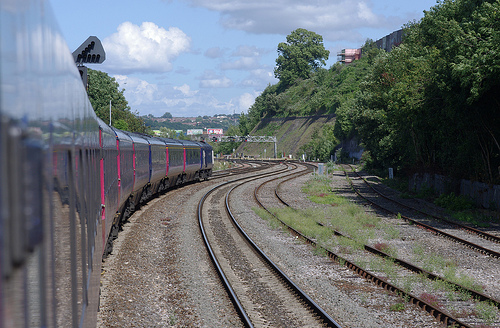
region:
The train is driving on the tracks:
[36, 63, 303, 289]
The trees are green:
[323, 54, 494, 201]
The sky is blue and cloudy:
[86, 17, 297, 139]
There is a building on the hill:
[314, 29, 436, 84]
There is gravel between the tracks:
[206, 196, 412, 306]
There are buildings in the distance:
[158, 118, 243, 146]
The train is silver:
[149, 135, 249, 198]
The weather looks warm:
[66, 17, 427, 282]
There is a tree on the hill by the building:
[265, 26, 367, 111]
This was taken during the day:
[66, 21, 313, 193]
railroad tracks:
[80, 212, 267, 322]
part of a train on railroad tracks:
[0, 3, 214, 326]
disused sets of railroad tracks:
[260, 175, 455, 273]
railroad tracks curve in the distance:
[215, 155, 310, 195]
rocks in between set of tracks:
[215, 220, 245, 275]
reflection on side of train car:
[5, 96, 110, 291]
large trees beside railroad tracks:
[356, 5, 493, 241]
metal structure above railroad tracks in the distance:
[183, 128, 294, 168]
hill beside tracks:
[255, 22, 492, 190]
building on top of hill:
[327, 38, 397, 88]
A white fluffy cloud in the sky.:
[103, 17, 192, 78]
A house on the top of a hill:
[336, 40, 368, 66]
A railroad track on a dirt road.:
[195, 202, 311, 326]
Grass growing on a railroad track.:
[269, 178, 427, 278]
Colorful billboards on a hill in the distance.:
[181, 119, 226, 139]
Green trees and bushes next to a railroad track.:
[356, 36, 491, 183]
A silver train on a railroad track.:
[87, 105, 213, 210]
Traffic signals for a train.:
[206, 125, 281, 152]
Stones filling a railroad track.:
[142, 210, 202, 323]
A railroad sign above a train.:
[71, 35, 111, 68]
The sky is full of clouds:
[126, 29, 266, 96]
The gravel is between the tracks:
[243, 182, 399, 326]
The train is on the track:
[66, 90, 271, 207]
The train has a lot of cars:
[59, 113, 243, 197]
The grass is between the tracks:
[284, 195, 368, 291]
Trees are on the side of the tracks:
[369, 87, 483, 189]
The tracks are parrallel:
[203, 176, 463, 326]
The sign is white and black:
[70, 33, 143, 94]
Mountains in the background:
[157, 104, 267, 145]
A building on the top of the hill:
[334, 39, 381, 74]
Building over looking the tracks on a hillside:
[333, 40, 363, 69]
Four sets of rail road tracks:
[50, 113, 497, 325]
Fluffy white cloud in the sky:
[83, 11, 203, 94]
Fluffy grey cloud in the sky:
[196, 1, 385, 41]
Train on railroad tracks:
[0, 1, 225, 326]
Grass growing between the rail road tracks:
[253, 203, 371, 264]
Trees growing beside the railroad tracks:
[348, 16, 498, 195]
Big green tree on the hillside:
[273, 20, 330, 87]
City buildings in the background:
[143, 113, 248, 139]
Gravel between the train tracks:
[208, 208, 323, 327]